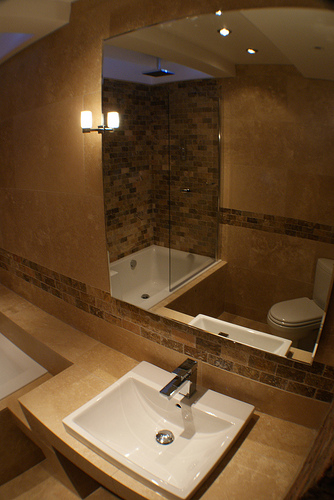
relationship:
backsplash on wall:
[0, 248, 333, 404] [0, 1, 333, 431]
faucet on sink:
[158, 356, 199, 399] [61, 352, 262, 498]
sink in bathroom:
[61, 352, 262, 498] [0, 0, 333, 499]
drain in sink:
[154, 428, 174, 445] [61, 352, 262, 498]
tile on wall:
[83, 286, 105, 304] [67, 243, 116, 341]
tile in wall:
[168, 134, 200, 181] [148, 95, 301, 240]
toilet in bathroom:
[262, 245, 329, 339] [3, 40, 329, 346]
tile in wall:
[77, 283, 138, 313] [4, 78, 115, 284]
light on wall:
[78, 105, 97, 129] [16, 52, 112, 303]